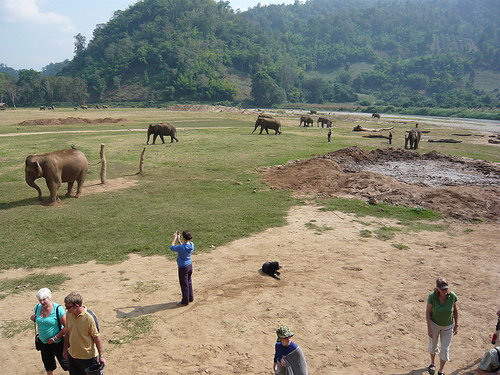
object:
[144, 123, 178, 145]
elephant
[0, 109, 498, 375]
field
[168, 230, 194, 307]
woman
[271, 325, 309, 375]
boy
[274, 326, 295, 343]
hat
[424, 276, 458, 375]
woman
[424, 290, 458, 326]
shirt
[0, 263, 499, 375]
ground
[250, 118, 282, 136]
elephants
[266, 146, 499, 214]
watering hole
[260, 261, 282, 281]
dog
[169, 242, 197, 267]
shirt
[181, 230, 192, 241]
hair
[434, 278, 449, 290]
visor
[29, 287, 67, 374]
woman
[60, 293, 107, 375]
man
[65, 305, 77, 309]
sunglasses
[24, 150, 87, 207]
elephant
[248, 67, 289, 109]
trees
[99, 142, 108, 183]
tree stump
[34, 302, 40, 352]
handbag